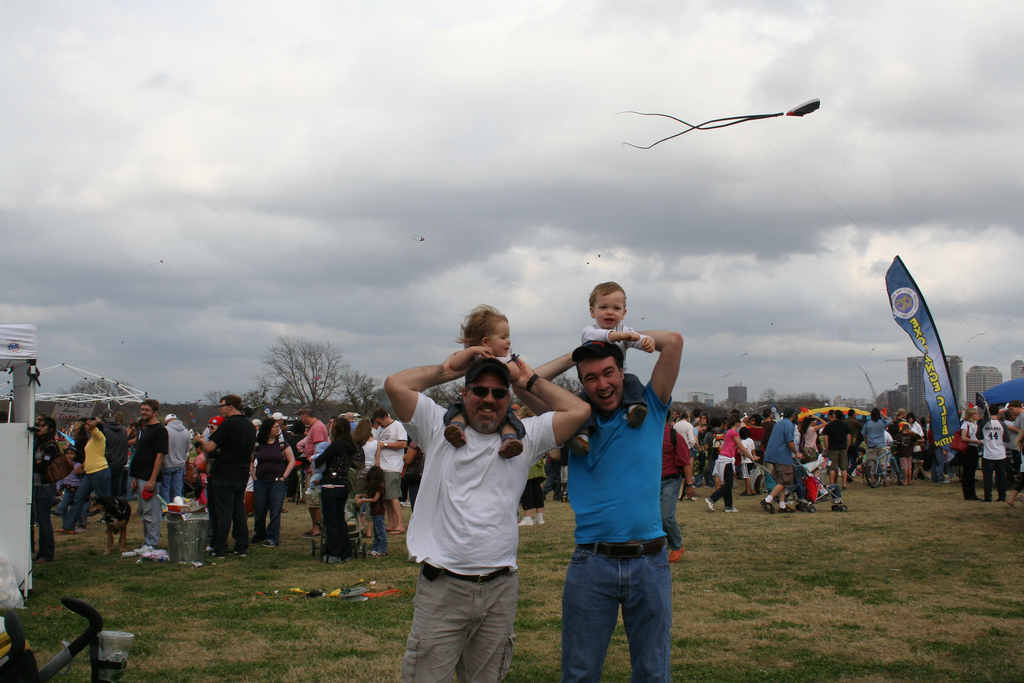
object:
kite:
[591, 68, 971, 199]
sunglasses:
[432, 372, 532, 403]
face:
[467, 378, 510, 426]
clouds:
[0, 85, 323, 305]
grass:
[0, 496, 1017, 673]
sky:
[0, 92, 1012, 398]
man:
[370, 354, 599, 609]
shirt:
[384, 390, 572, 580]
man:
[110, 385, 177, 568]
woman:
[702, 413, 765, 519]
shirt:
[709, 423, 764, 459]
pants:
[693, 452, 756, 520]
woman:
[25, 406, 83, 569]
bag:
[25, 438, 96, 491]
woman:
[939, 388, 984, 521]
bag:
[938, 423, 981, 460]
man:
[751, 381, 804, 531]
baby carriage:
[774, 444, 854, 518]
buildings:
[673, 349, 1024, 422]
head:
[438, 351, 537, 441]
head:
[547, 328, 663, 420]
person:
[561, 273, 691, 455]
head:
[581, 273, 652, 335]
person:
[426, 298, 537, 462]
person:
[309, 409, 378, 562]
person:
[239, 387, 303, 554]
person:
[58, 397, 129, 534]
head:
[452, 305, 522, 357]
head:
[323, 407, 356, 442]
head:
[198, 385, 263, 428]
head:
[139, 396, 166, 423]